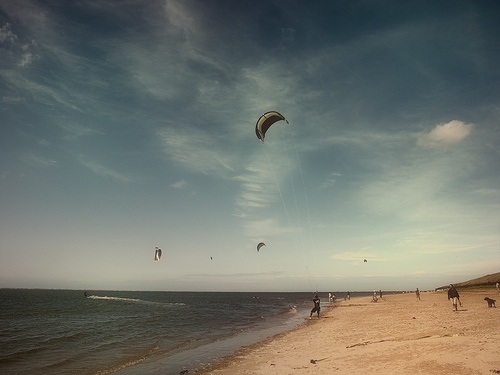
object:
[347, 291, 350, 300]
person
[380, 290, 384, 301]
person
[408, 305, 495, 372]
beach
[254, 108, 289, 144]
parasail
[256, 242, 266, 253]
parasail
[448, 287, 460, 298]
jacket.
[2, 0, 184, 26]
sky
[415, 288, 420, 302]
people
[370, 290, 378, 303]
people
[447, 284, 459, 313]
people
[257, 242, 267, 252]
kite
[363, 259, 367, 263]
kite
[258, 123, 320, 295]
string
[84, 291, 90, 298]
man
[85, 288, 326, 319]
water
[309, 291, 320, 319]
man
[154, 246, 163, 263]
parasail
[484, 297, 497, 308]
dog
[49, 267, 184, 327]
ocean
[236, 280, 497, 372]
shore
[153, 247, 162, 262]
kite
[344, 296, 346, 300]
person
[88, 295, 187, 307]
trail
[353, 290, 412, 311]
sand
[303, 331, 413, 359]
sand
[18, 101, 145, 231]
sky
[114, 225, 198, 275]
sky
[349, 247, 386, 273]
sky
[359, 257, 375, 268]
parasail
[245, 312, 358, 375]
beach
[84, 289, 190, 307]
waves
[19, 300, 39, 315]
water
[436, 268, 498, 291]
hill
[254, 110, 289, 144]
kite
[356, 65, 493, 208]
sky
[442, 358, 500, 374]
sand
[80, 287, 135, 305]
wake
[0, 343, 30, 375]
water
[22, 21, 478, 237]
clouds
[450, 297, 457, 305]
capris